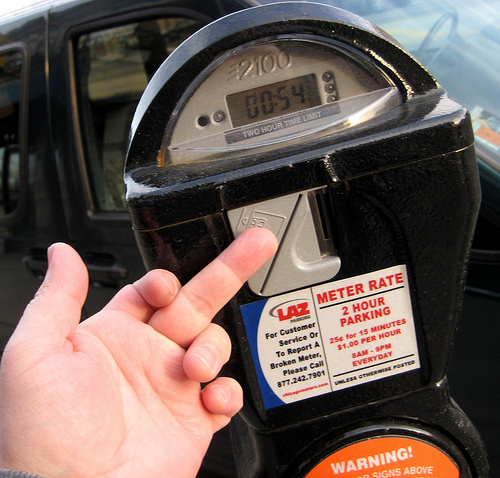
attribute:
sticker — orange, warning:
[302, 434, 461, 477]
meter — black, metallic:
[121, 0, 489, 477]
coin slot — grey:
[258, 193, 304, 298]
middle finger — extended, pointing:
[147, 226, 279, 353]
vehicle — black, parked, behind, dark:
[1, 0, 499, 477]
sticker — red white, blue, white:
[237, 263, 423, 411]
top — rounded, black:
[113, 0, 445, 170]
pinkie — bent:
[200, 375, 245, 423]